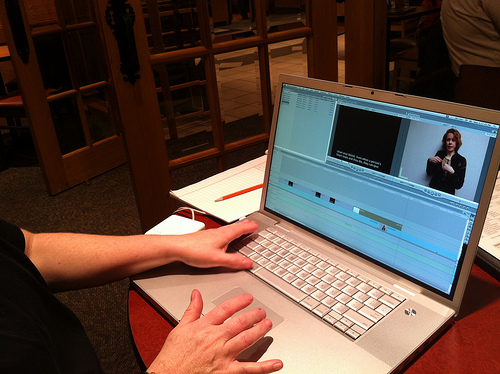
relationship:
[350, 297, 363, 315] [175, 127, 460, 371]
button on keyboard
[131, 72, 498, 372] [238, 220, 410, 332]
laptop has keyboard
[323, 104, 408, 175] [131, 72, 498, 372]
black screen on laptop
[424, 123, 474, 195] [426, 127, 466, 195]
image of a image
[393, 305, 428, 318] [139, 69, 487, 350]
stick on lap top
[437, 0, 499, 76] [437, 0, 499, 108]
shirt on man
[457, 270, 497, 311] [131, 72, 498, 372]
shadow on laptop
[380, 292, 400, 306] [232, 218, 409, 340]
button on keyboard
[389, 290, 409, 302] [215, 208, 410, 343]
button on keyboard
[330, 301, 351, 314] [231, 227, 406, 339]
button on keyboard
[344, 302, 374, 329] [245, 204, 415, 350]
button on keyboard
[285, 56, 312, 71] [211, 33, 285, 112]
tile on floor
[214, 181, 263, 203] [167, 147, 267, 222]
pencil on paper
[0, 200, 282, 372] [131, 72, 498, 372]
person sitting in front of laptop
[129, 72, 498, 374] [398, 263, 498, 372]
laptop on table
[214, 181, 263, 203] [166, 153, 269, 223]
pencil on papers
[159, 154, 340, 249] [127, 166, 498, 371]
papers on table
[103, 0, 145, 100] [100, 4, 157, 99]
handle on door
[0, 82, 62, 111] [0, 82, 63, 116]
cushion on chair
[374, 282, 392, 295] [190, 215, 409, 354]
silver button on keyboard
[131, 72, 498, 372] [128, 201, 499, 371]
laptop on table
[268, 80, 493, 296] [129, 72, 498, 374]
screen on laptop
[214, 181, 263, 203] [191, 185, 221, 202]
pencil and paper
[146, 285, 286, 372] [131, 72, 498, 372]
hand on a laptop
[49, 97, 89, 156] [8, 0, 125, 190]
glass pane on door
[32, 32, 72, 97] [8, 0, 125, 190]
glass pane on door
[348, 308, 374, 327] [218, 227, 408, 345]
button on keyboard